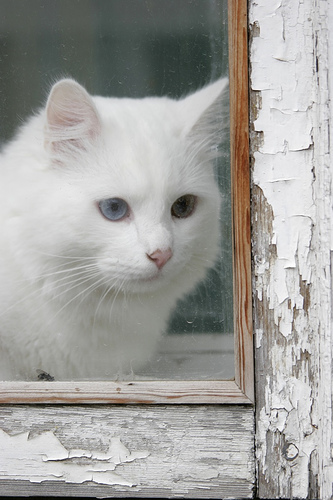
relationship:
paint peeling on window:
[255, 0, 332, 500] [0, 0, 251, 403]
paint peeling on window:
[255, 171, 320, 318] [0, 3, 315, 496]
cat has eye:
[0, 73, 231, 380] [95, 197, 130, 222]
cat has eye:
[0, 73, 231, 380] [169, 194, 197, 219]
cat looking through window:
[0, 73, 231, 380] [0, 0, 251, 403]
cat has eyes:
[3, 60, 231, 383] [90, 190, 202, 224]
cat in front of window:
[0, 73, 231, 380] [0, 0, 251, 403]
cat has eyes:
[0, 73, 231, 380] [87, 188, 206, 225]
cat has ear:
[0, 73, 231, 380] [40, 76, 105, 167]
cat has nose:
[0, 73, 231, 380] [136, 233, 174, 264]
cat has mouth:
[0, 73, 231, 380] [106, 269, 176, 293]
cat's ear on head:
[44, 77, 100, 166] [83, 105, 244, 300]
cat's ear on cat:
[44, 77, 100, 166] [40, 100, 199, 370]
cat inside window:
[0, 73, 231, 380] [0, 3, 315, 496]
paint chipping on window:
[255, 0, 332, 500] [0, 3, 315, 496]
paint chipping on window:
[6, 404, 325, 496] [0, 0, 251, 403]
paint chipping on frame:
[255, 0, 332, 500] [239, 89, 311, 204]